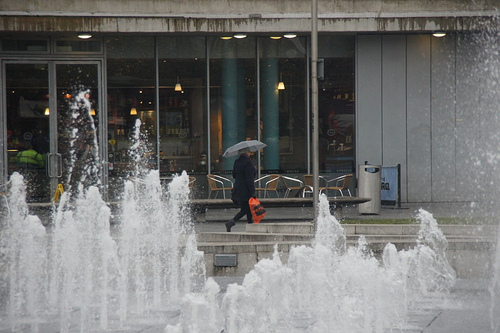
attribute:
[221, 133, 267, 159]
umbrella — open, light grey, dark grey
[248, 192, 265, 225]
bag — bright orange, orange, red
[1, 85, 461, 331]
water fountain — outdoors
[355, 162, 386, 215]
trash can — tan, gray, metal, silver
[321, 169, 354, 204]
chair — brown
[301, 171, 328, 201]
chair — brown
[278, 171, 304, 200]
chair — brown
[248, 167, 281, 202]
chair — brown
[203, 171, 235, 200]
chair — brown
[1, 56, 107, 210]
door — glass, tall, large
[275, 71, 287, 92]
lamp — circular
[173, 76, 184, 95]
lamp — circular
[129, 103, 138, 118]
lamp — circular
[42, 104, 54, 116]
lamp — circular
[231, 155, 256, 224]
outfit — black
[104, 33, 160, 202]
window — tall, glass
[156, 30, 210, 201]
window — tall, glass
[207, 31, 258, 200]
window — tall, glass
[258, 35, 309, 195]
window — tall, glass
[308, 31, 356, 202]
window — tall, glass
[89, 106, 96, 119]
lamp — circular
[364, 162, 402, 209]
sign — powder blue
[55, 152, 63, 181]
handle — silver, metal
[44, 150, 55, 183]
handle — metal, silver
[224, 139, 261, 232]
woman — passing, walking, in black